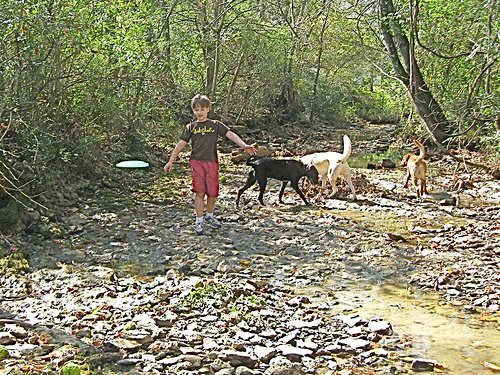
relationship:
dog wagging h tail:
[398, 136, 428, 195] [418, 134, 437, 162]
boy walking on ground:
[162, 90, 258, 235] [128, 227, 324, 362]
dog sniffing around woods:
[398, 136, 428, 195] [3, 3, 484, 370]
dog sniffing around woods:
[277, 134, 357, 196] [3, 3, 484, 370]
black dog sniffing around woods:
[233, 155, 323, 203] [3, 3, 484, 370]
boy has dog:
[162, 90, 258, 235] [403, 135, 446, 199]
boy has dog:
[162, 90, 258, 235] [244, 155, 281, 208]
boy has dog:
[162, 90, 258, 235] [306, 132, 363, 205]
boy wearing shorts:
[168, 85, 215, 229] [187, 163, 214, 198]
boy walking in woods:
[162, 90, 258, 235] [1, 2, 496, 234]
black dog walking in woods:
[233, 155, 323, 203] [1, 2, 496, 234]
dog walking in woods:
[277, 134, 357, 196] [1, 2, 496, 234]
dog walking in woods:
[398, 136, 428, 195] [1, 2, 496, 234]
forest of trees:
[132, 34, 172, 84] [0, 0, 499, 217]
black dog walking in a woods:
[233, 155, 323, 203] [3, 3, 484, 370]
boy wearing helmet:
[162, 90, 258, 235] [181, 118, 231, 165]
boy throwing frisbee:
[162, 90, 258, 235] [115, 157, 151, 170]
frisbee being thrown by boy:
[112, 159, 150, 171] [162, 81, 249, 235]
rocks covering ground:
[102, 206, 420, 320] [13, 102, 486, 344]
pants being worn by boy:
[187, 156, 219, 198] [165, 87, 255, 205]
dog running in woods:
[398, 136, 428, 195] [3, 3, 484, 370]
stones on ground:
[118, 327, 148, 340] [0, 119, 485, 373]